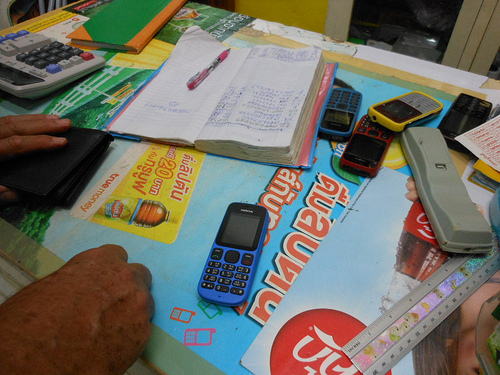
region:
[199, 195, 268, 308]
blue phone on a table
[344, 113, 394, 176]
red phone on a table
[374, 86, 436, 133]
yellow cell phone on a table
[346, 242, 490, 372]
white ruler on a table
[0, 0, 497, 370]
cardboard taped to a table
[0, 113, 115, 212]
black wallet in a person's hand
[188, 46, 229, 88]
red pen laying on an open book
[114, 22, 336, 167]
an open book with a red pen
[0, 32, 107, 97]
calculator laying on the table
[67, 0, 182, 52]
green and orange notebook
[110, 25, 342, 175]
an open notebook on the desk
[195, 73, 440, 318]
cellphones are on the desk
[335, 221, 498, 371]
a ruler is in the desk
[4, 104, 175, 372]
a person is sitting at the desk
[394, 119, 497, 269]
a remote control is on the desk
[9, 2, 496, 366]
assorted papers on the desk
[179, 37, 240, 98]
a pen is on the open book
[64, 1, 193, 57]
a green and orange book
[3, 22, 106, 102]
a calculator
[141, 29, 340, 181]
there is writing inside the open notebook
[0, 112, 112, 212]
Fingers on a black leather wallet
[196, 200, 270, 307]
Blue Nokia cellphone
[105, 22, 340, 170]
Open ledger with blue pen writing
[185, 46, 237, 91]
Red retractable ballpoint pen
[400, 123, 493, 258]
Gray remote control laying upside down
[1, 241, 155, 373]
Man's hand with curled under fingers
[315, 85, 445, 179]
Three cellphones laying on a desk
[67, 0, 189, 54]
Closed green book with orange binding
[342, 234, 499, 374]
Ruler with colorful designs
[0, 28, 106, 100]
Grey desk calculator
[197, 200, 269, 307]
a blue cell phone with black buttons resting on a table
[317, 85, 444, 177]
a group of three colorful cell phones laying next to each other on a table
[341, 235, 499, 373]
a white plastic ruler sitting on a table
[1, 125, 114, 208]
a man's black wallet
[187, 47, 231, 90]
a writing ink pen with pink shell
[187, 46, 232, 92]
pink colored writing pen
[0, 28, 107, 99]
a gray colored calculator with large buttons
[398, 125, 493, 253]
a remote control laying upside down on a table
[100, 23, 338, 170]
a notebook resting on a table with writing on it from an ink pen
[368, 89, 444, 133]
cellphone that is yellow resting on a desk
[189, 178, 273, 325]
This is a cell phone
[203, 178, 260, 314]
The cell phone is blue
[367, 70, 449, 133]
This cell phone is yellow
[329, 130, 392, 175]
This cell phone is red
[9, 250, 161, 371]
This is a person's hand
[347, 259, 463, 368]
This is a ruler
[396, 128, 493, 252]
This is a remote control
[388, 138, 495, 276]
The remote is gray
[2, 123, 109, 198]
This is a wallet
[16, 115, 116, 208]
The wallet is black